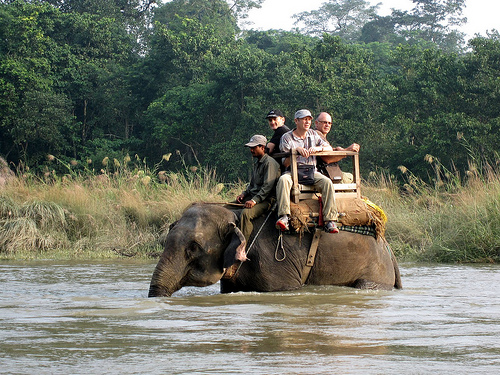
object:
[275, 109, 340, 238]
man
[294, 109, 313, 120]
gray hat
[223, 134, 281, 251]
man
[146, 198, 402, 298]
elephant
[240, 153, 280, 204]
shirt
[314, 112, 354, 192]
man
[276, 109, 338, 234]
man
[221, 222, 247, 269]
ear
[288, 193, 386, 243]
blanket elephant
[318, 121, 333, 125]
glasses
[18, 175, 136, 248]
weeds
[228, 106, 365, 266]
men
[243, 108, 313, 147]
hats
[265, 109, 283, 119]
black hat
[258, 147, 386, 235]
saddle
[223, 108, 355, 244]
four men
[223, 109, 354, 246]
people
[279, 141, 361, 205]
structure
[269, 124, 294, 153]
shirt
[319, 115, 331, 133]
face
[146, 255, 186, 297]
trunk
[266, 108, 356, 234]
passengers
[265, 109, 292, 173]
man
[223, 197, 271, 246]
pants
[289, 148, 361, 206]
crate